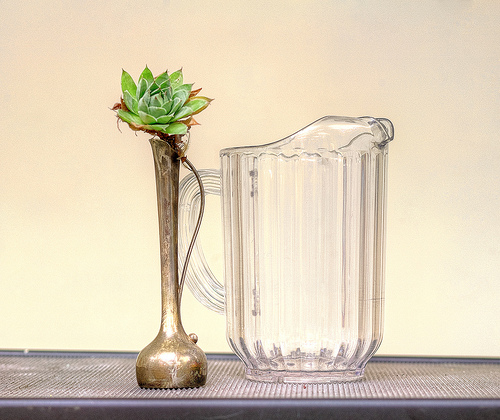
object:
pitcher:
[178, 115, 394, 382]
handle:
[179, 168, 226, 313]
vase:
[136, 138, 206, 388]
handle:
[180, 141, 204, 301]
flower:
[110, 64, 215, 137]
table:
[0, 350, 499, 419]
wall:
[2, 1, 499, 357]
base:
[136, 330, 206, 389]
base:
[247, 369, 366, 382]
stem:
[160, 133, 180, 148]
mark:
[168, 364, 177, 385]